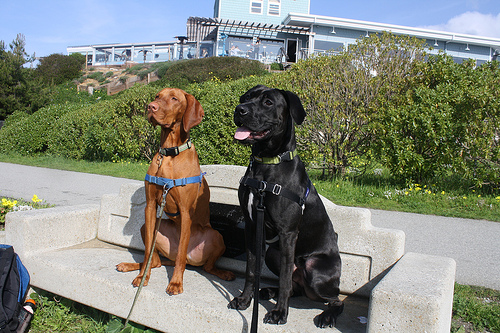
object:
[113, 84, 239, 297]
dog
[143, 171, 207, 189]
harness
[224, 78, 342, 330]
dog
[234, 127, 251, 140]
tongue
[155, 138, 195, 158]
collar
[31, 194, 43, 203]
flower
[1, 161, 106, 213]
sidewalk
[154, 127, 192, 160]
neck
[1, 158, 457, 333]
bench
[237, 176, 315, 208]
harness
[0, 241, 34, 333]
backpack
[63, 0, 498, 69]
building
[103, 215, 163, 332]
leash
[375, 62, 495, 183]
bush